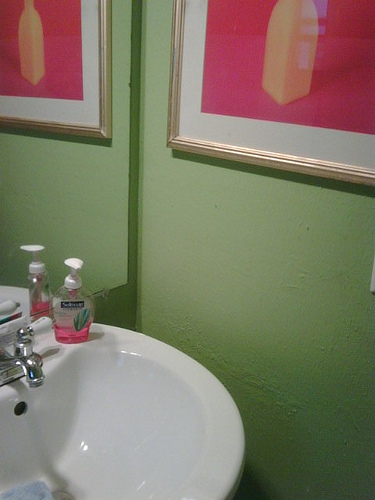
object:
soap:
[50, 256, 95, 343]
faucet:
[3, 322, 46, 390]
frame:
[165, 0, 373, 189]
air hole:
[12, 399, 30, 416]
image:
[0, 0, 115, 146]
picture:
[163, 0, 372, 192]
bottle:
[48, 257, 97, 347]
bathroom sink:
[0, 314, 249, 498]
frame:
[164, 0, 193, 152]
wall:
[138, 0, 375, 499]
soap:
[52, 323, 90, 342]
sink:
[0, 317, 247, 499]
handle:
[16, 320, 36, 343]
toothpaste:
[1, 317, 23, 380]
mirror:
[1, 0, 133, 327]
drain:
[23, 432, 192, 495]